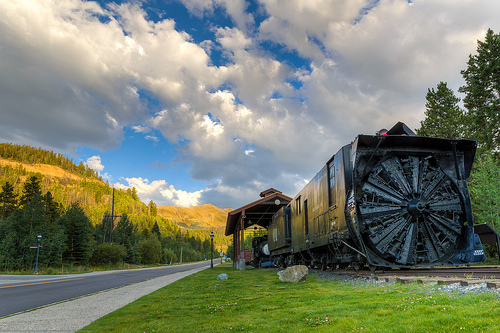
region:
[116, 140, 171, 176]
this is the sky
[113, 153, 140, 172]
the sky is blue in color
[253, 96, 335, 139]
these are the clouds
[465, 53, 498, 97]
this is a tree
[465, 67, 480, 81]
the leaves are green in color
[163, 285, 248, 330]
this is a grass area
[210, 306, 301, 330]
the grass is green in color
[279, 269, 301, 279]
this is a stone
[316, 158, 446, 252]
this is a train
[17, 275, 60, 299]
this is a road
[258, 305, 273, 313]
the grass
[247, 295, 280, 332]
the grass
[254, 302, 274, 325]
the grass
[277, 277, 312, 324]
the grass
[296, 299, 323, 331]
the grass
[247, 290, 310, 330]
the grass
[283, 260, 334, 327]
the grass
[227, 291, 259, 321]
the grass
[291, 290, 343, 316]
the grass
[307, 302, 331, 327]
the grass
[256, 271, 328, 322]
the grass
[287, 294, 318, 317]
the grass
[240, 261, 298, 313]
the grass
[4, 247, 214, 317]
the road is empty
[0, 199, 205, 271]
pine trees along the road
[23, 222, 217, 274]
light posts along the road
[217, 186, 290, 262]
the train station is wood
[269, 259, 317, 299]
a large rock in the grass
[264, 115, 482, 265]
a large black train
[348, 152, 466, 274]
some kind of fan on the train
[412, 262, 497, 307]
rail road tracks and ties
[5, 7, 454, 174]
the sky is mostly cloudy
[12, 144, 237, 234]
the sun is shining on the hills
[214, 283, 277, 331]
the grass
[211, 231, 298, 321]
the grass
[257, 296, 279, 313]
the grass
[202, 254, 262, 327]
the grass